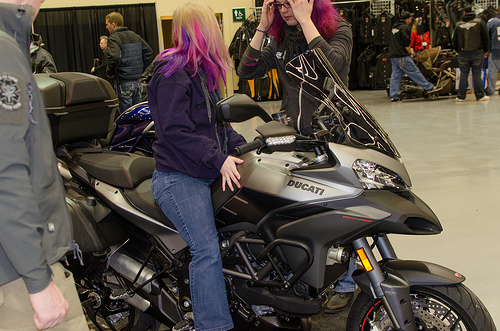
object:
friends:
[236, 0, 356, 129]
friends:
[142, 1, 250, 331]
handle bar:
[232, 135, 267, 157]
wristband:
[255, 28, 267, 33]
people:
[388, 8, 500, 103]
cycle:
[34, 57, 500, 331]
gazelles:
[286, 179, 325, 196]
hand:
[219, 155, 244, 192]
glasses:
[272, 2, 291, 9]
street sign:
[355, 247, 373, 272]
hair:
[158, 3, 224, 73]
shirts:
[353, 12, 393, 90]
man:
[450, 3, 491, 101]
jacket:
[451, 17, 490, 54]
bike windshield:
[283, 48, 400, 159]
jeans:
[150, 168, 237, 331]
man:
[385, 11, 443, 102]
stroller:
[398, 46, 459, 101]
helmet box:
[33, 72, 121, 145]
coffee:
[100, 35, 109, 42]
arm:
[237, 25, 272, 77]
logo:
[286, 179, 325, 195]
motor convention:
[0, 0, 499, 331]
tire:
[344, 282, 500, 330]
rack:
[330, 0, 399, 91]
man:
[103, 10, 154, 115]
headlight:
[352, 159, 406, 190]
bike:
[50, 78, 495, 330]